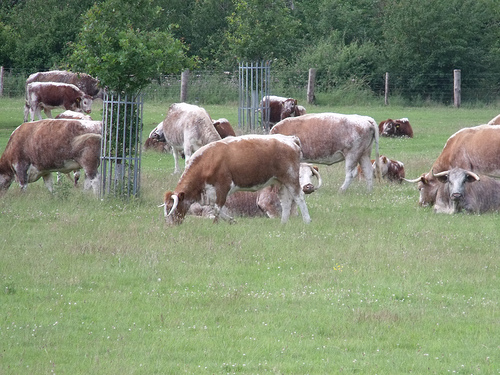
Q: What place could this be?
A: It is a field.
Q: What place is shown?
A: It is a field.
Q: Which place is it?
A: It is a field.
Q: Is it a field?
A: Yes, it is a field.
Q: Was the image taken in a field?
A: Yes, it was taken in a field.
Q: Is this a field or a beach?
A: It is a field.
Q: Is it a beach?
A: No, it is a field.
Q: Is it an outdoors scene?
A: Yes, it is outdoors.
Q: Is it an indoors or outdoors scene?
A: It is outdoors.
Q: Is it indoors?
A: No, it is outdoors.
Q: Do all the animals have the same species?
A: Yes, all the animals are cows.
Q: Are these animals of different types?
A: No, all the animals are cows.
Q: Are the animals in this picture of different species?
A: No, all the animals are cows.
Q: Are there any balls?
A: No, there are no balls.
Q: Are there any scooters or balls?
A: No, there are no balls or scooters.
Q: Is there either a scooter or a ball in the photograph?
A: No, there are no balls or scooters.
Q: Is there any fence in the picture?
A: Yes, there is a fence.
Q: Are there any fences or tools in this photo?
A: Yes, there is a fence.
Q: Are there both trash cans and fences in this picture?
A: No, there is a fence but no trash cans.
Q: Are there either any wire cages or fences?
A: Yes, there is a wire fence.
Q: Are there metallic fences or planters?
A: Yes, there is a metal fence.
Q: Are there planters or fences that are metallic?
A: Yes, the fence is metallic.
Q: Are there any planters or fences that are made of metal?
A: Yes, the fence is made of metal.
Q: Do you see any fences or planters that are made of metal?
A: Yes, the fence is made of metal.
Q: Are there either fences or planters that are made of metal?
A: Yes, the fence is made of metal.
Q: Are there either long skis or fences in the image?
A: Yes, there is a long fence.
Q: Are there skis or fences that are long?
A: Yes, the fence is long.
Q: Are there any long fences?
A: Yes, there is a long fence.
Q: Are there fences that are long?
A: Yes, there is a fence that is long.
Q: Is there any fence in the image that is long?
A: Yes, there is a fence that is long.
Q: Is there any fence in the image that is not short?
A: Yes, there is a long fence.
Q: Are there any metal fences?
A: Yes, there is a metal fence.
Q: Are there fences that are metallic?
A: Yes, there is a fence that is metallic.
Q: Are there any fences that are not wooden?
A: Yes, there is a metallic fence.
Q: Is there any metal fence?
A: Yes, there is a fence that is made of metal.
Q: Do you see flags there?
A: No, there are no flags.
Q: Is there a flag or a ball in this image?
A: No, there are no flags or balls.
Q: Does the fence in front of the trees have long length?
A: Yes, the fence is long.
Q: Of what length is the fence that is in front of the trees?
A: The fence is long.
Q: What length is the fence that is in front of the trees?
A: The fence is long.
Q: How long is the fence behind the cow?
A: The fence is long.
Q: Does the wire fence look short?
A: No, the fence is long.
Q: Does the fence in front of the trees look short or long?
A: The fence is long.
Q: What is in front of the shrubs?
A: The fence is in front of the shrubs.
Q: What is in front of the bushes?
A: The fence is in front of the shrubs.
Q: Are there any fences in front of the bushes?
A: Yes, there is a fence in front of the bushes.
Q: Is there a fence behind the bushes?
A: No, the fence is in front of the bushes.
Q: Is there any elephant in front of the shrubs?
A: No, there is a fence in front of the shrubs.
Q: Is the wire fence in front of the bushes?
A: Yes, the fence is in front of the bushes.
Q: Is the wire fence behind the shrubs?
A: No, the fence is in front of the shrubs.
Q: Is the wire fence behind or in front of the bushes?
A: The fence is in front of the bushes.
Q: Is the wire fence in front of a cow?
A: No, the fence is behind a cow.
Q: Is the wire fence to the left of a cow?
A: No, the fence is to the right of a cow.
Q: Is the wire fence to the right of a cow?
A: Yes, the fence is to the right of a cow.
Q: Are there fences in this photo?
A: Yes, there is a fence.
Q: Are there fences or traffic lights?
A: Yes, there is a fence.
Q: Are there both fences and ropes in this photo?
A: No, there is a fence but no ropes.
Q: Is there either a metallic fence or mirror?
A: Yes, there is a metal fence.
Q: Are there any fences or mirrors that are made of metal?
A: Yes, the fence is made of metal.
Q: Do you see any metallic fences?
A: Yes, there is a metal fence.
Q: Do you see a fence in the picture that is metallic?
A: Yes, there is a fence that is metallic.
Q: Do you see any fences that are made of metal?
A: Yes, there is a fence that is made of metal.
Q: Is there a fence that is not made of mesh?
A: Yes, there is a fence that is made of metal.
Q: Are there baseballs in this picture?
A: No, there are no baseballs.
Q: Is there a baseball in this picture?
A: No, there are no baseballs.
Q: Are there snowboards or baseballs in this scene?
A: No, there are no baseballs or snowboards.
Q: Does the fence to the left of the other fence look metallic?
A: Yes, the fence is metallic.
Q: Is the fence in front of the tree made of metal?
A: Yes, the fence is made of metal.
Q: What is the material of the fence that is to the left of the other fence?
A: The fence is made of metal.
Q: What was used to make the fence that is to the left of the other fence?
A: The fence is made of metal.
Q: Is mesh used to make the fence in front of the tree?
A: No, the fence is made of metal.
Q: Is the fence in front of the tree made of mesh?
A: No, the fence is made of metal.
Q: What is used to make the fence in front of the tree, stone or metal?
A: The fence is made of metal.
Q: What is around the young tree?
A: The fence is around the tree.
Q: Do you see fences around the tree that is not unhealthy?
A: Yes, there is a fence around the tree.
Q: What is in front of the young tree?
A: The fence is in front of the tree.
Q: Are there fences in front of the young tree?
A: Yes, there is a fence in front of the tree.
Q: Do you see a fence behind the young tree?
A: No, the fence is in front of the tree.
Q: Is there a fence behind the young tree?
A: No, the fence is in front of the tree.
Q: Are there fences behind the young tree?
A: No, the fence is in front of the tree.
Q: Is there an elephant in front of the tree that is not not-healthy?
A: No, there is a fence in front of the tree.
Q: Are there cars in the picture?
A: No, there are no cars.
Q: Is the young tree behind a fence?
A: Yes, the tree is behind a fence.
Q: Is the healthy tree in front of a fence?
A: No, the tree is behind a fence.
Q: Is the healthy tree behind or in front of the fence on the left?
A: The tree is behind the fence.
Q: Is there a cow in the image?
A: Yes, there is a cow.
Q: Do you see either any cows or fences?
A: Yes, there is a cow.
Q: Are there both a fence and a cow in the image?
A: Yes, there are both a cow and a fence.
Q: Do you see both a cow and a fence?
A: Yes, there are both a cow and a fence.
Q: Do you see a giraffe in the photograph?
A: No, there are no giraffes.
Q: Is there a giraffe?
A: No, there are no giraffes.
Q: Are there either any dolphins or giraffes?
A: No, there are no giraffes or dolphins.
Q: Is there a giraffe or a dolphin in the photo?
A: No, there are no giraffes or dolphins.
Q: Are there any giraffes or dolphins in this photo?
A: No, there are no giraffes or dolphins.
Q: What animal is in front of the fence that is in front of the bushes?
A: The cow is in front of the fence.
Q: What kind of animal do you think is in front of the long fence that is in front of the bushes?
A: The animal is a cow.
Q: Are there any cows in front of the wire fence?
A: Yes, there is a cow in front of the fence.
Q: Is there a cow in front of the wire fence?
A: Yes, there is a cow in front of the fence.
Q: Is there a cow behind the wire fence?
A: No, the cow is in front of the fence.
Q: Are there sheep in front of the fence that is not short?
A: No, there is a cow in front of the fence.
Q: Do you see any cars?
A: No, there are no cars.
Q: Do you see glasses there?
A: No, there are no glasses.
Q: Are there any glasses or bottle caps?
A: No, there are no glasses or bottle caps.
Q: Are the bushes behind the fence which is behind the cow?
A: Yes, the bushes are behind the fence.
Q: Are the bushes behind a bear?
A: No, the bushes are behind the fence.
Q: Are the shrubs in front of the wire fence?
A: No, the shrubs are behind the fence.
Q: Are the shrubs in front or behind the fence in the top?
A: The shrubs are behind the fence.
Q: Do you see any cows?
A: Yes, there is a cow.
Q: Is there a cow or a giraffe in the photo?
A: Yes, there is a cow.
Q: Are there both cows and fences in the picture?
A: Yes, there are both a cow and a fence.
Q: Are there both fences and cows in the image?
A: Yes, there are both a cow and a fence.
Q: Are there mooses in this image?
A: No, there are no mooses.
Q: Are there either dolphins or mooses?
A: No, there are no mooses or dolphins.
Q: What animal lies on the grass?
A: The cow lies on the grass.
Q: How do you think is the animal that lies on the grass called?
A: The animal is a cow.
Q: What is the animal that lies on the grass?
A: The animal is a cow.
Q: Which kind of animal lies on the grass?
A: The animal is a cow.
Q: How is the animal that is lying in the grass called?
A: The animal is a cow.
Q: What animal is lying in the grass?
A: The animal is a cow.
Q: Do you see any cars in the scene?
A: No, there are no cars.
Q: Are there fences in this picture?
A: Yes, there is a fence.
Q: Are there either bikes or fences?
A: Yes, there is a fence.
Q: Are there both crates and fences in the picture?
A: No, there is a fence but no crates.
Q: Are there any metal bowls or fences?
A: Yes, there is a metal fence.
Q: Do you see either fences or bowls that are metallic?
A: Yes, the fence is metallic.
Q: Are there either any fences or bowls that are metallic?
A: Yes, the fence is metallic.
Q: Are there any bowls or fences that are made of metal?
A: Yes, the fence is made of metal.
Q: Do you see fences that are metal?
A: Yes, there is a metal fence.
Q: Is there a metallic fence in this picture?
A: Yes, there is a metal fence.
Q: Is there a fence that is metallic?
A: Yes, there is a fence that is metallic.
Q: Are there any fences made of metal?
A: Yes, there is a fence that is made of metal.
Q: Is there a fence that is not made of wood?
A: Yes, there is a fence that is made of metal.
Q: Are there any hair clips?
A: No, there are no hair clips.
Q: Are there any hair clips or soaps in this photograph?
A: No, there are no hair clips or soaps.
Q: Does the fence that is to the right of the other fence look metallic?
A: Yes, the fence is metallic.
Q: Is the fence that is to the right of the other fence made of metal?
A: Yes, the fence is made of metal.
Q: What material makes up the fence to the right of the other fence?
A: The fence is made of metal.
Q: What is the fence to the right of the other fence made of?
A: The fence is made of metal.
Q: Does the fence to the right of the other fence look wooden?
A: No, the fence is metallic.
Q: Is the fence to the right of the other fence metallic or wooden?
A: The fence is metallic.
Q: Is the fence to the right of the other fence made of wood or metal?
A: The fence is made of metal.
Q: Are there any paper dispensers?
A: No, there are no paper dispensers.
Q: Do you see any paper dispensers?
A: No, there are no paper dispensers.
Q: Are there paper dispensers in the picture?
A: No, there are no paper dispensers.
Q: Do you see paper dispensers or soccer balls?
A: No, there are no paper dispensers or soccer balls.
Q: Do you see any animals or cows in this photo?
A: Yes, there is a cow.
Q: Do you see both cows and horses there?
A: No, there is a cow but no horses.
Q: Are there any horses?
A: No, there are no horses.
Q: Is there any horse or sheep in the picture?
A: No, there are no horses or sheep.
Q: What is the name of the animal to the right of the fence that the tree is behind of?
A: The animal is a cow.